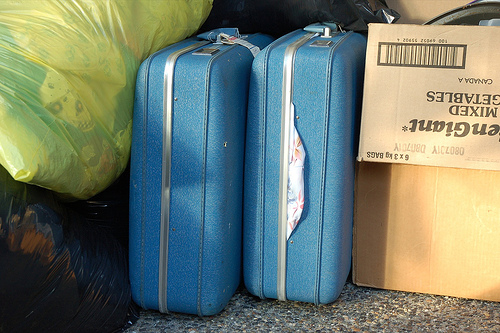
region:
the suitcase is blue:
[89, 4, 231, 311]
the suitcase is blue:
[246, 28, 343, 329]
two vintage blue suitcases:
[116, 20, 407, 329]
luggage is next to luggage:
[130, 26, 275, 318]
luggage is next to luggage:
[241, 20, 368, 304]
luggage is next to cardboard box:
[352, 24, 497, 301]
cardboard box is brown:
[350, 20, 498, 301]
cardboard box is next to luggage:
[350, 24, 498, 304]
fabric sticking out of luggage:
[287, 99, 306, 239]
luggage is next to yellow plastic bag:
[129, 24, 273, 316]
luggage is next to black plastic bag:
[126, 27, 275, 317]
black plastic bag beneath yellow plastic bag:
[0, 165, 138, 331]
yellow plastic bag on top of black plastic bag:
[2, 2, 212, 195]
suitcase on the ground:
[258, 25, 363, 315]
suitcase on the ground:
[124, 37, 236, 320]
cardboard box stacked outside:
[346, 17, 496, 183]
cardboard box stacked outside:
[352, 176, 496, 306]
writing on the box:
[449, 73, 494, 87]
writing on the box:
[400, 117, 464, 142]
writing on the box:
[366, 150, 413, 165]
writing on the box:
[431, 141, 461, 154]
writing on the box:
[405, 115, 491, 133]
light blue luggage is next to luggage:
[125, 26, 269, 313]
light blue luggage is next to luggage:
[242, 20, 366, 304]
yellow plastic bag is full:
[0, 2, 212, 198]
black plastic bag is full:
[2, 171, 133, 332]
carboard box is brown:
[352, 159, 497, 301]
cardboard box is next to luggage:
[355, 163, 497, 305]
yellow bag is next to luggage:
[0, 0, 216, 201]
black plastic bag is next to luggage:
[0, 174, 132, 331]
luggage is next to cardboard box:
[241, 22, 368, 302]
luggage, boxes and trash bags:
[38, 8, 468, 297]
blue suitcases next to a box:
[131, 5, 497, 319]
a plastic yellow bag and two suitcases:
[4, 6, 347, 322]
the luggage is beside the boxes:
[139, 11, 496, 318]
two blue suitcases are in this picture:
[141, 32, 373, 332]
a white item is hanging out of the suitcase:
[279, 102, 312, 244]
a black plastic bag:
[2, 178, 147, 330]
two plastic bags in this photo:
[2, 7, 132, 332]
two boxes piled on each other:
[364, 21, 494, 314]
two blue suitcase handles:
[192, 10, 342, 47]